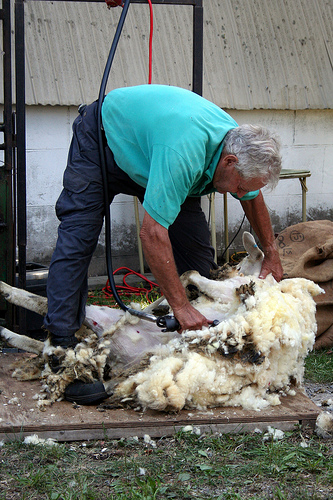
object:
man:
[44, 82, 280, 372]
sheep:
[0, 260, 321, 411]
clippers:
[155, 316, 219, 332]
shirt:
[104, 84, 257, 208]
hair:
[226, 124, 282, 180]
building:
[1, 0, 332, 277]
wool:
[130, 277, 317, 409]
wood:
[0, 363, 323, 446]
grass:
[0, 438, 332, 499]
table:
[211, 168, 309, 252]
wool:
[315, 413, 330, 436]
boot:
[49, 341, 107, 406]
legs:
[42, 299, 140, 341]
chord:
[93, 0, 164, 324]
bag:
[270, 219, 333, 350]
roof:
[0, 0, 332, 110]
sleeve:
[144, 146, 202, 230]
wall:
[24, 106, 54, 256]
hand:
[261, 251, 284, 282]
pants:
[45, 129, 110, 337]